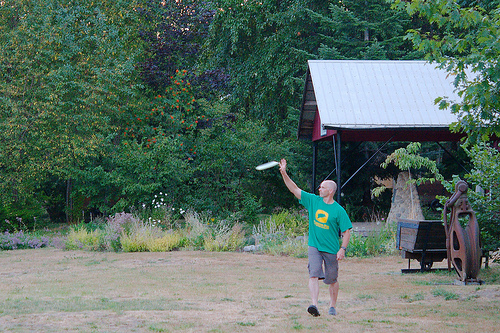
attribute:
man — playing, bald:
[278, 155, 349, 318]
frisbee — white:
[256, 160, 279, 173]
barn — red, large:
[285, 50, 495, 226]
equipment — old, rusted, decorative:
[401, 180, 484, 281]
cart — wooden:
[399, 219, 448, 267]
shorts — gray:
[310, 244, 340, 284]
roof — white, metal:
[297, 58, 498, 137]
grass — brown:
[4, 246, 429, 330]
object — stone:
[392, 170, 426, 230]